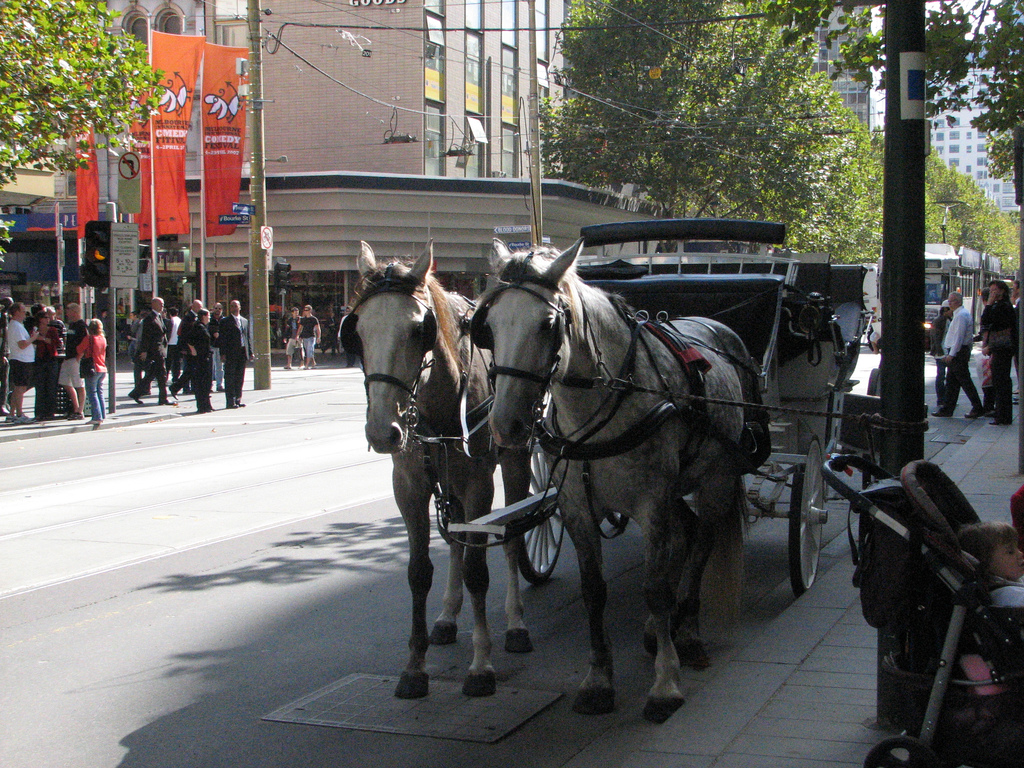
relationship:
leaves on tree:
[706, 89, 795, 157] [567, 9, 1023, 278]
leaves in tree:
[965, 206, 996, 239] [948, 189, 1018, 259]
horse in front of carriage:
[466, 223, 776, 725] [438, 208, 888, 591]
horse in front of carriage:
[343, 229, 558, 705] [438, 208, 888, 591]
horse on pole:
[343, 229, 557, 705] [822, 130, 970, 541]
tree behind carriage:
[521, 22, 893, 245] [480, 234, 878, 665]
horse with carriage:
[466, 223, 776, 725] [575, 186, 943, 543]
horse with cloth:
[466, 223, 776, 725] [610, 297, 788, 412]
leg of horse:
[388, 497, 462, 690] [343, 229, 558, 705]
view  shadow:
[12, 17, 993, 672] [202, 522, 498, 751]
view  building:
[30, 21, 1020, 631] [244, 38, 636, 339]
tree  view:
[516, 0, 865, 256] [12, 17, 993, 672]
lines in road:
[40, 460, 296, 659] [64, 356, 868, 746]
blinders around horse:
[337, 287, 448, 365] [343, 229, 557, 705]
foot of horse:
[384, 669, 512, 715] [315, 209, 728, 689]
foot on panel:
[384, 669, 512, 715] [272, 622, 545, 743]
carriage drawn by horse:
[529, 175, 843, 567] [343, 229, 557, 705]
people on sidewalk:
[4, 263, 283, 411] [2, 360, 258, 464]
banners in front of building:
[155, 36, 236, 224] [4, 36, 298, 415]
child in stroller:
[943, 527, 1023, 603] [823, 449, 1018, 743]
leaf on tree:
[740, 39, 831, 109] [583, 36, 1020, 318]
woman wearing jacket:
[88, 313, 115, 426] [80, 326, 111, 370]